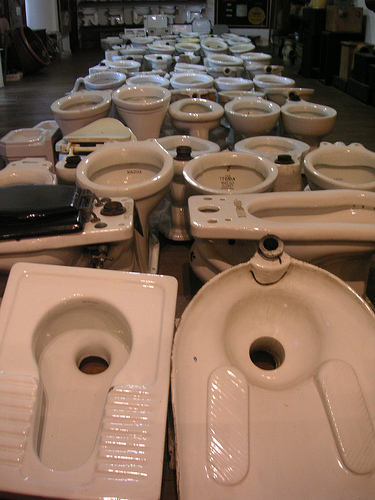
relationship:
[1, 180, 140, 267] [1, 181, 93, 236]
toilet with lid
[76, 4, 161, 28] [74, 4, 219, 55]
toilet bowls on wall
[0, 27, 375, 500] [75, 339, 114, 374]
toilet bowl with hole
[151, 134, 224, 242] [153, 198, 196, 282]
toilet bowl on floor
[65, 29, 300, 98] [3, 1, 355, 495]
toilets in room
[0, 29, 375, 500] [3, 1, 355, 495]
toilets in room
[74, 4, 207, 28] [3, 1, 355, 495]
toilets in room